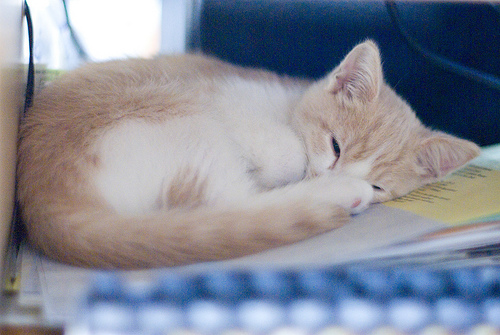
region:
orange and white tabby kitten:
[15, 36, 484, 273]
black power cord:
[18, 0, 36, 120]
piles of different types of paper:
[3, 140, 498, 323]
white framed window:
[46, 0, 188, 72]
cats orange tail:
[20, 205, 352, 269]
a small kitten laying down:
[18, 40, 480, 267]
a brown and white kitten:
[19, 40, 481, 265]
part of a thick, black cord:
[384, 3, 495, 91]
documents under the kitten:
[17, 146, 498, 322]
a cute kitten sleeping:
[18, 42, 483, 272]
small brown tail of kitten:
[33, 202, 347, 271]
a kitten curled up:
[24, 38, 478, 268]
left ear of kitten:
[331, 40, 377, 105]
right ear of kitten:
[403, 132, 479, 179]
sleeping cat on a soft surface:
[0, 36, 477, 265]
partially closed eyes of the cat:
[325, 130, 389, 202]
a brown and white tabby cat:
[20, 39, 481, 264]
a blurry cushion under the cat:
[14, 258, 498, 330]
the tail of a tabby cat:
[23, 173, 369, 268]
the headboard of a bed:
[0, 0, 47, 310]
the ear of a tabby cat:
[331, 38, 383, 103]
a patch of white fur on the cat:
[88, 83, 295, 213]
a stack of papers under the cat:
[198, 146, 496, 271]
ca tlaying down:
[128, 33, 424, 296]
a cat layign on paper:
[117, 58, 489, 300]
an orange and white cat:
[71, 34, 489, 277]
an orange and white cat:
[107, 45, 410, 240]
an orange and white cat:
[41, 62, 351, 319]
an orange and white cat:
[162, 100, 394, 241]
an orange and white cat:
[47, 43, 361, 276]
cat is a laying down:
[30, 23, 484, 318]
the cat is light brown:
[14, 11, 456, 276]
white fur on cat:
[103, 83, 280, 208]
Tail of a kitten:
[34, 195, 356, 262]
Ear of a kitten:
[329, 32, 390, 114]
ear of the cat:
[316, 28, 416, 103]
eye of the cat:
[291, 102, 378, 183]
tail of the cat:
[36, 150, 378, 292]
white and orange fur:
[69, 70, 302, 175]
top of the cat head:
[342, 83, 432, 160]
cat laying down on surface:
[16, 76, 453, 258]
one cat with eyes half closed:
[6, 32, 459, 250]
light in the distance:
[81, 4, 159, 51]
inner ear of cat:
[408, 142, 471, 179]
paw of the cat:
[312, 168, 384, 236]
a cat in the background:
[65, 26, 498, 301]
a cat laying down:
[39, 40, 461, 293]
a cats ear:
[279, 6, 490, 181]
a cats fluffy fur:
[32, 26, 494, 275]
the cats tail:
[12, 137, 496, 302]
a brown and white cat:
[38, 18, 498, 270]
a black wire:
[5, 4, 102, 312]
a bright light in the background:
[50, 0, 193, 70]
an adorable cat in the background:
[98, 5, 484, 306]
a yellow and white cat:
[14, 50, 490, 287]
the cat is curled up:
[1, 30, 486, 282]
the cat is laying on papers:
[7, 42, 472, 289]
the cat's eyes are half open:
[318, 120, 390, 202]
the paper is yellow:
[377, 150, 499, 233]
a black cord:
[9, 0, 44, 115]